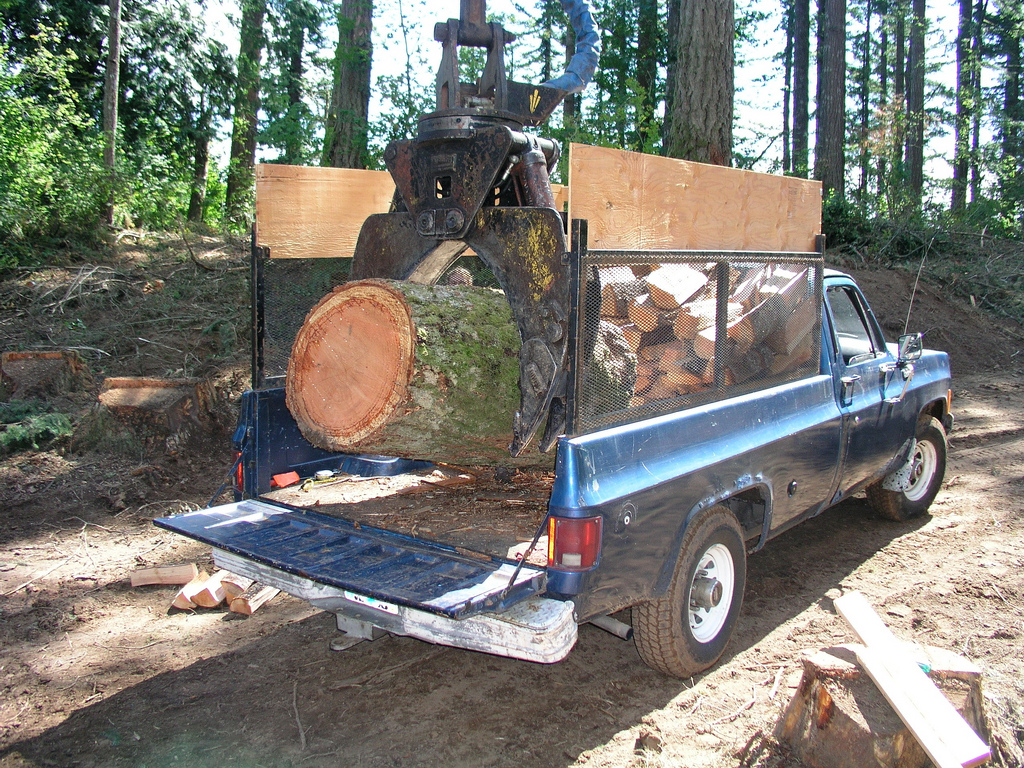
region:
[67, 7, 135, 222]
a tree in the woods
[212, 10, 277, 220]
a tree in the woods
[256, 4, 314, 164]
a tree in the woods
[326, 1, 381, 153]
a tree in the woods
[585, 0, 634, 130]
a tree in the woods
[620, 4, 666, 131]
a tree in the woods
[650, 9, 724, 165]
a tree in the woods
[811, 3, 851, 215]
a tree in the woods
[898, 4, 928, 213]
a tree in the woods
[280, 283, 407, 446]
bottom of a log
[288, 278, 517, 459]
log in a truck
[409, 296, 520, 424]
moss on the trunk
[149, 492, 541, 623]
the back is down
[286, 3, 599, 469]
claw grabbing a log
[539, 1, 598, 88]
the wire is blue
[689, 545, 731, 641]
hub cap is white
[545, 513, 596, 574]
the light is off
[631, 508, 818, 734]
a view of tire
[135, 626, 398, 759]
a view of shadow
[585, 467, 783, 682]
tire of the van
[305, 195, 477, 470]
a view of wood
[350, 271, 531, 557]
wood in the van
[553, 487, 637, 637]
a view of indicators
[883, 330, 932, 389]
chrome mirror on blue truck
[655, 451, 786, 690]
white wheels on blue truck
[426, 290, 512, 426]
green moss on tree stump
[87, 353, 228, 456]
sunlight shinning on tree stump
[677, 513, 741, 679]
chrome center cap on white wheel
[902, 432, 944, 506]
chrome center cap on white wheel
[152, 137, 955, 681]
A blue pickup truck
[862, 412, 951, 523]
front tire is black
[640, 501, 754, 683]
back tire is black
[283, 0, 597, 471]
machine claw holding a log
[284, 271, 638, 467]
the log is large and greenish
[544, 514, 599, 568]
tail light is red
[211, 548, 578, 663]
the bumper is rubber and white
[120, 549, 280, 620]
pile of wood on the dirt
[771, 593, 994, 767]
plank of wood on a stump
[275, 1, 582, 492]
rusty crane arm grabbing tree trunk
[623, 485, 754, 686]
tire covered in dirt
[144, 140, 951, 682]
blye pick up truck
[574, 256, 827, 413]
chopped wood sitting in back of pick up truck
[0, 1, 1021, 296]
tall trees with green leaves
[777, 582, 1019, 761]
plank leaning up against stump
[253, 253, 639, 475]
tree trunk segment covered in moss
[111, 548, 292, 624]
chopped wood on the ground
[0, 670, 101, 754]
a patch of dirt with twigs and branches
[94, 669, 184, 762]
a patch of dirt with twigs and branches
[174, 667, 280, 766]
a patch of dirt with twigs and branches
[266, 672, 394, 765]
a patch of dirt with twigs and branches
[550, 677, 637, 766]
a patch of dirt with twigs and branches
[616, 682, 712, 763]
a patch of dirt with twigs and branches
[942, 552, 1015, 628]
a patch of dirt with twigs and branches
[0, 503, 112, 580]
a patch of dirt with twigs and branches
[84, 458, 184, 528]
a patch of dirt with twigs and branches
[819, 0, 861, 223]
A tree in the woods.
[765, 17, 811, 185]
A tree in the woods.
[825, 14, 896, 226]
A tree in the woods.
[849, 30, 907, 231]
A tree in the woods.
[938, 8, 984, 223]
A tree in the woods.